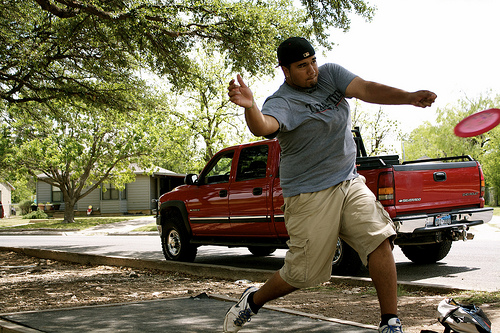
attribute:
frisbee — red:
[454, 108, 500, 138]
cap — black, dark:
[275, 37, 316, 68]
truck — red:
[155, 138, 288, 263]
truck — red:
[353, 126, 495, 262]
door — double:
[185, 141, 273, 241]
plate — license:
[432, 212, 452, 225]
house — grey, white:
[30, 161, 183, 218]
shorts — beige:
[278, 173, 396, 288]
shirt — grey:
[261, 64, 358, 197]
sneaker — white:
[223, 285, 261, 331]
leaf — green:
[195, 47, 201, 52]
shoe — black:
[379, 319, 402, 332]